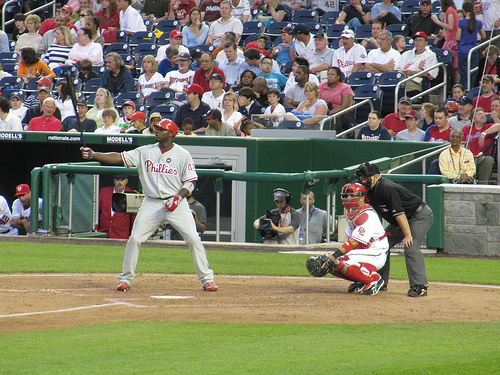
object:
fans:
[2, 4, 474, 134]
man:
[253, 188, 301, 241]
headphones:
[268, 185, 291, 209]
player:
[75, 112, 216, 293]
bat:
[63, 71, 87, 150]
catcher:
[319, 182, 389, 301]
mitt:
[304, 252, 335, 279]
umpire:
[355, 152, 435, 302]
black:
[372, 178, 425, 226]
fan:
[313, 68, 351, 110]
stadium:
[1, 1, 491, 362]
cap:
[408, 32, 429, 39]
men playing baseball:
[303, 161, 432, 297]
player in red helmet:
[149, 117, 178, 135]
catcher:
[353, 164, 432, 297]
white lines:
[1, 281, 144, 327]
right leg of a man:
[168, 199, 220, 291]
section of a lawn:
[198, 329, 377, 375]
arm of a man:
[74, 147, 142, 166]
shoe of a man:
[199, 280, 220, 292]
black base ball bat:
[305, 253, 335, 279]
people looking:
[282, 22, 500, 154]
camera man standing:
[251, 187, 298, 251]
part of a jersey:
[138, 173, 195, 201]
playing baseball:
[73, 114, 219, 291]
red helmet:
[336, 179, 373, 220]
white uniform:
[77, 116, 248, 303]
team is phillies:
[80, 117, 220, 292]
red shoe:
[114, 276, 135, 294]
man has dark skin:
[77, 117, 225, 307]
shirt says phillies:
[123, 145, 200, 207]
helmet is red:
[151, 117, 180, 152]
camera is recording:
[104, 192, 143, 214]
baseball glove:
[162, 195, 182, 214]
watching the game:
[6, 4, 499, 149]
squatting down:
[357, 161, 435, 298]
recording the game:
[252, 184, 302, 248]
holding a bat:
[61, 70, 93, 158]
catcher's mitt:
[313, 241, 354, 274]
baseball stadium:
[7, 133, 498, 366]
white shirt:
[339, 207, 386, 262]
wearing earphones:
[268, 188, 293, 210]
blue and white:
[40, 43, 73, 67]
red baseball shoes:
[109, 276, 221, 292]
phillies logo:
[143, 161, 181, 178]